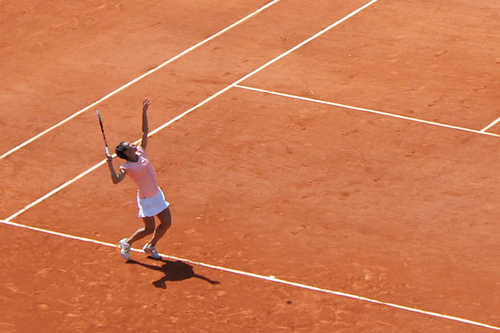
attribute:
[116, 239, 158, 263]
shoes — white, tennis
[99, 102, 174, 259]
woman — tennis player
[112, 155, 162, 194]
shirt — pink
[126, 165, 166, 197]
shirt — pink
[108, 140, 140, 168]
hair — black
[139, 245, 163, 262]
shoe — white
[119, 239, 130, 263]
shoe — white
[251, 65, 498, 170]
line — white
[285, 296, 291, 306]
shadow — ball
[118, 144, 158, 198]
shirt — pink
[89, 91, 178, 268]
player — tennis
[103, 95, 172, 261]
woman — playing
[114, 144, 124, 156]
hair — short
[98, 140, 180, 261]
woman — black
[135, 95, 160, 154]
arm — raised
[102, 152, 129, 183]
arm — raised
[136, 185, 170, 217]
skirt — white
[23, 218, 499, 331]
line — white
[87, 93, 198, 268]
woman — tennis player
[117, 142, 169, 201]
shirt — pink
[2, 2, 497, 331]
lines — white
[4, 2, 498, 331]
tennis court — clay, clay-colored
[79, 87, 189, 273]
woman — preparing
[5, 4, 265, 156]
line — white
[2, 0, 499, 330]
court — clay, orange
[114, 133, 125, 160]
hair — short